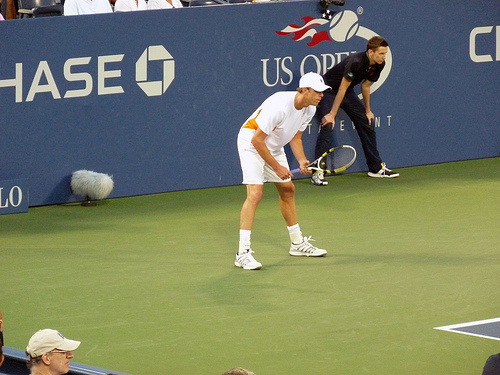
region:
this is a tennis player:
[223, 70, 337, 290]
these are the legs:
[235, 178, 312, 268]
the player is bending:
[233, 67, 331, 262]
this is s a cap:
[305, 73, 330, 91]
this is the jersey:
[275, 101, 301, 135]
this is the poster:
[144, 26, 224, 146]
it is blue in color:
[180, 82, 234, 143]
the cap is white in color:
[298, 72, 330, 87]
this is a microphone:
[73, 166, 110, 203]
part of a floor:
[243, 286, 268, 312]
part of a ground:
[344, 310, 371, 342]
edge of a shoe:
[242, 260, 268, 297]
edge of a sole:
[249, 263, 259, 275]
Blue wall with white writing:
[0, 0, 497, 212]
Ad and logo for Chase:
[1, 43, 179, 103]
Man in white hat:
[23, 326, 81, 374]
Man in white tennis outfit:
[232, 71, 357, 273]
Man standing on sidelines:
[310, 36, 400, 186]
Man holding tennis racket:
[284, 144, 357, 176]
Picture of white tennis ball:
[326, 8, 360, 43]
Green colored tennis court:
[0, 156, 498, 373]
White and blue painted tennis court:
[433, 315, 498, 341]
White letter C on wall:
[467, 21, 494, 65]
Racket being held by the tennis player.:
[290, 145, 355, 173]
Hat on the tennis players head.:
[298, 71, 330, 92]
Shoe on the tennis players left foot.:
[287, 236, 326, 256]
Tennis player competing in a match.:
[235, 70, 328, 269]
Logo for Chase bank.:
[135, 45, 173, 97]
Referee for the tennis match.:
[309, 37, 399, 178]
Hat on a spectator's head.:
[25, 328, 80, 357]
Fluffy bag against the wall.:
[70, 168, 112, 199]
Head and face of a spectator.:
[25, 327, 72, 374]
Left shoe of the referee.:
[365, 161, 400, 176]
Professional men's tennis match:
[15, 17, 489, 367]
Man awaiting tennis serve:
[230, 62, 360, 279]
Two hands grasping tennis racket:
[274, 142, 363, 182]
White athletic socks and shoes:
[230, 222, 329, 273]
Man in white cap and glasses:
[23, 328, 82, 373]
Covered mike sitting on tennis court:
[58, 167, 118, 211]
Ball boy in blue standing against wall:
[311, 32, 406, 189]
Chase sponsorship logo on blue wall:
[0, 39, 185, 111]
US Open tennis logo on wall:
[258, 11, 400, 99]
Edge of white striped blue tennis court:
[434, 317, 498, 347]